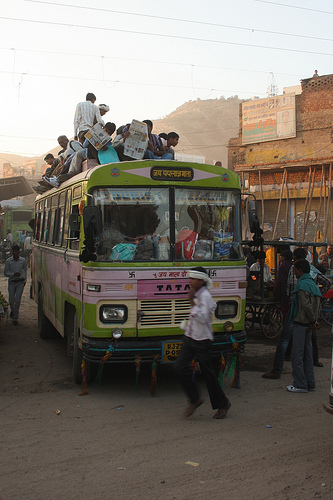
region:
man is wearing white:
[92, 237, 209, 436]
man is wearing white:
[117, 190, 262, 387]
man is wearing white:
[138, 284, 277, 485]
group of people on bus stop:
[55, 98, 192, 198]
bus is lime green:
[81, 301, 143, 335]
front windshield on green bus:
[98, 186, 240, 270]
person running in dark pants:
[178, 332, 246, 407]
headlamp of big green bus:
[93, 303, 126, 319]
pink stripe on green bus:
[67, 252, 154, 309]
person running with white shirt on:
[179, 282, 222, 344]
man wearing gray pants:
[296, 255, 320, 401]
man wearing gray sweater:
[297, 273, 332, 335]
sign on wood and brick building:
[240, 105, 317, 172]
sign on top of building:
[238, 95, 306, 148]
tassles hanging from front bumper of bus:
[72, 328, 263, 398]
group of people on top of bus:
[38, 92, 203, 197]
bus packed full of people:
[24, 91, 264, 396]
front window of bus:
[82, 179, 245, 276]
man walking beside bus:
[4, 241, 31, 327]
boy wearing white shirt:
[181, 264, 227, 359]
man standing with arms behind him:
[282, 258, 326, 399]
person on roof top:
[310, 66, 319, 78]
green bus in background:
[3, 206, 39, 238]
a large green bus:
[27, 145, 257, 379]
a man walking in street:
[170, 260, 234, 419]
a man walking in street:
[0, 241, 27, 323]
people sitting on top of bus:
[41, 96, 179, 185]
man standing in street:
[281, 255, 319, 394]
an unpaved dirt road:
[6, 274, 329, 494]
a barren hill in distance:
[123, 94, 251, 154]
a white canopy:
[0, 172, 32, 203]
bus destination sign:
[145, 164, 193, 180]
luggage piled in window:
[106, 231, 234, 261]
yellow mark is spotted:
[185, 459, 197, 472]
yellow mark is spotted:
[185, 457, 194, 463]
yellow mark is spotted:
[188, 457, 196, 466]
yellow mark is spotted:
[188, 458, 195, 478]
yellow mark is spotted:
[190, 453, 199, 474]